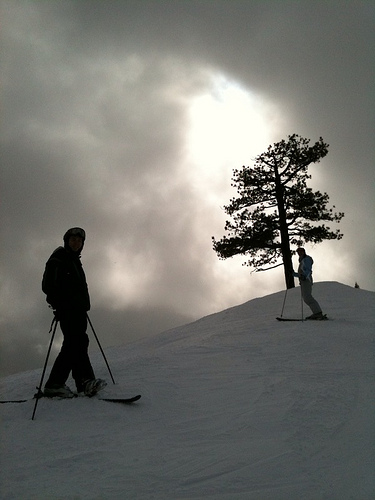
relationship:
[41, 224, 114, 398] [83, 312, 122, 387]
skier holding ski pole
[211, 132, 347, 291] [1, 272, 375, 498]
tree on top of mountain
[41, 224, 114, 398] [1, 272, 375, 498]
skier on top of mountain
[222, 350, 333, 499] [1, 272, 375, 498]
snow on top of mountain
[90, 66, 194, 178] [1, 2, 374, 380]
clouds in sky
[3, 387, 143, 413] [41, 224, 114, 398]
skis on skier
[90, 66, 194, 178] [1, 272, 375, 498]
clouds above mountain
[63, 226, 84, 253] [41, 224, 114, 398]
head of skier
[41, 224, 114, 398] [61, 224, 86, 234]
skier wearing helmet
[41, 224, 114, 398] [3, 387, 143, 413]
skier wearing skis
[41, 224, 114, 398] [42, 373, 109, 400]
skier wearing boots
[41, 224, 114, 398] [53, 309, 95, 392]
skier wearing pants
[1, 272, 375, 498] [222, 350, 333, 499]
mountain covered in snow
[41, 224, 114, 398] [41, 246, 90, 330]
skier wearing jacket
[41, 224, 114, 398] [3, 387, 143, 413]
skier on top of skis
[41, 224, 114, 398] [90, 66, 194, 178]
skier under clouds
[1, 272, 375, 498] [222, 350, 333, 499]
mountain covered with snow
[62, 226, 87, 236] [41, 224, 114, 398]
goggles on skier